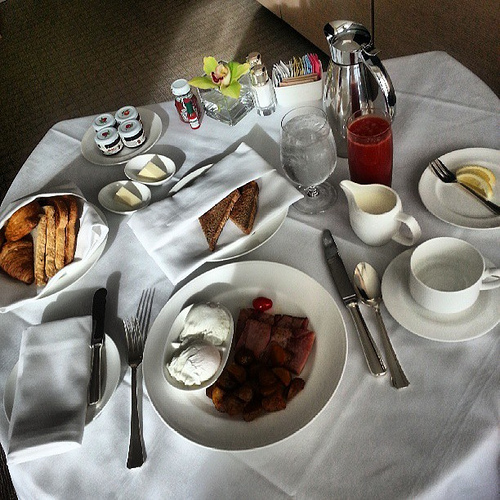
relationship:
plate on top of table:
[131, 254, 350, 452] [0, 48, 500, 497]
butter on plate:
[135, 163, 164, 177] [120, 150, 176, 186]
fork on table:
[123, 287, 153, 473] [0, 48, 500, 497]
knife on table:
[84, 286, 112, 406] [0, 48, 500, 497]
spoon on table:
[352, 258, 414, 393] [0, 48, 500, 497]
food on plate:
[206, 296, 317, 422] [131, 254, 350, 452]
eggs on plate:
[167, 304, 232, 385] [131, 254, 350, 452]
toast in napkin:
[201, 178, 262, 248] [127, 141, 309, 287]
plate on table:
[131, 254, 350, 452] [0, 48, 500, 497]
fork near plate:
[123, 287, 153, 473] [131, 254, 350, 452]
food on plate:
[166, 296, 320, 423] [131, 254, 350, 452]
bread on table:
[2, 200, 36, 241] [0, 48, 500, 497]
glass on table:
[347, 111, 397, 188] [0, 48, 500, 497]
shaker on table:
[247, 74, 281, 117] [0, 48, 500, 497]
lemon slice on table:
[454, 165, 493, 200] [0, 48, 500, 497]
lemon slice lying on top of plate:
[454, 165, 493, 200] [415, 145, 485, 230]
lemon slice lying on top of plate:
[454, 165, 484, 183] [415, 145, 485, 230]